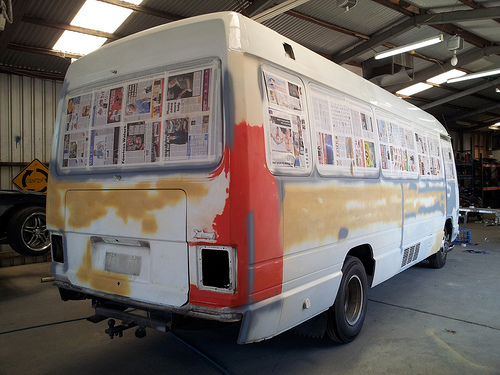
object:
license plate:
[100, 249, 144, 276]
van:
[42, 9, 459, 348]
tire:
[313, 253, 371, 345]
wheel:
[317, 251, 369, 347]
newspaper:
[63, 91, 93, 169]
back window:
[50, 57, 224, 178]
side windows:
[255, 62, 312, 179]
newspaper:
[262, 70, 313, 177]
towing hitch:
[101, 315, 137, 339]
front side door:
[438, 134, 458, 226]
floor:
[0, 217, 500, 375]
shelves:
[455, 158, 500, 168]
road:
[6, 250, 499, 375]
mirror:
[55, 61, 223, 173]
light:
[373, 32, 447, 60]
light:
[446, 62, 499, 87]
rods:
[373, 0, 499, 61]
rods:
[92, 0, 187, 21]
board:
[12, 155, 48, 194]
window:
[53, 57, 222, 169]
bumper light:
[50, 235, 65, 264]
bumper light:
[201, 248, 230, 289]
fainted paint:
[47, 49, 458, 345]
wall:
[3, 74, 62, 191]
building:
[1, 0, 500, 375]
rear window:
[56, 61, 220, 173]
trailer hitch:
[89, 301, 175, 342]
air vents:
[413, 243, 422, 262]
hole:
[47, 232, 66, 264]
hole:
[199, 246, 233, 288]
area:
[104, 252, 141, 277]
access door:
[63, 187, 191, 308]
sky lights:
[396, 82, 433, 101]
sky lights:
[66, 0, 136, 35]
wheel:
[427, 227, 450, 269]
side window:
[311, 87, 382, 179]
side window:
[376, 114, 420, 180]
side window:
[413, 130, 445, 181]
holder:
[91, 237, 153, 284]